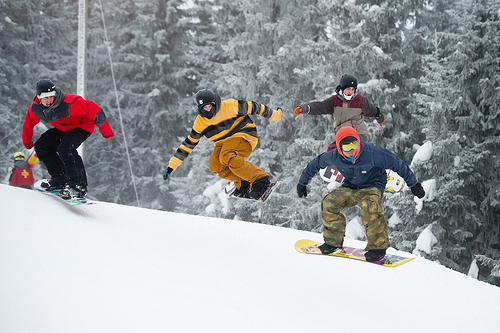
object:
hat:
[334, 125, 359, 163]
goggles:
[338, 142, 359, 152]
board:
[30, 179, 89, 207]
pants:
[205, 137, 272, 191]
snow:
[0, 182, 499, 332]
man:
[294, 126, 427, 264]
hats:
[337, 73, 358, 92]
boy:
[292, 125, 427, 262]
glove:
[161, 166, 173, 180]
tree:
[382, 28, 492, 277]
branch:
[471, 253, 499, 270]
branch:
[477, 183, 500, 214]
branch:
[411, 218, 445, 261]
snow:
[409, 140, 433, 169]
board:
[294, 236, 416, 267]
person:
[19, 78, 118, 200]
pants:
[32, 127, 91, 187]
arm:
[381, 149, 423, 185]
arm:
[296, 150, 328, 187]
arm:
[362, 96, 380, 120]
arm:
[307, 96, 328, 116]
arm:
[169, 120, 200, 171]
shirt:
[186, 113, 259, 138]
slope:
[0, 180, 498, 331]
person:
[290, 74, 387, 156]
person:
[6, 151, 36, 189]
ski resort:
[0, 0, 498, 333]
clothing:
[20, 94, 118, 151]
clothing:
[165, 98, 281, 171]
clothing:
[298, 95, 383, 143]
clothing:
[297, 141, 417, 192]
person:
[160, 88, 285, 203]